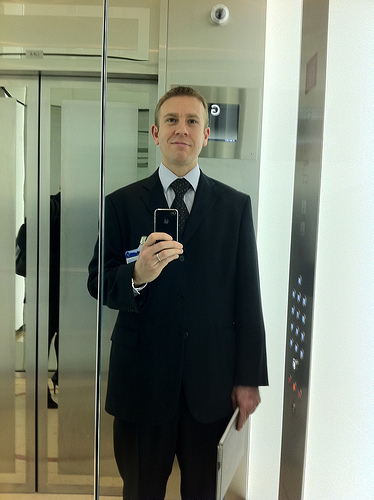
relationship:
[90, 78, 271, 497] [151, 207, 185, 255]
man holds phone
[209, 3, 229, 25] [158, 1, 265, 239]
camera attached to wall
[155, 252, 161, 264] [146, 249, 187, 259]
ring on finger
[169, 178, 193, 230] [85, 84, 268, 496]
tie worn by human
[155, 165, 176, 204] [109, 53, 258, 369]
shirt worn by human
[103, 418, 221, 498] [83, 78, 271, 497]
pants worn by man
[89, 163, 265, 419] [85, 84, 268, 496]
jacket worn by human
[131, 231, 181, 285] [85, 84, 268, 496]
hand belongs to human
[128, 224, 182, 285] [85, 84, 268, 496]
hand belongs to human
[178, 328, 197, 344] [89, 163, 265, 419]
button attached to jacket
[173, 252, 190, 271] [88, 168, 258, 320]
button attached to jacket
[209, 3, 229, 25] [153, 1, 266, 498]
camera on wall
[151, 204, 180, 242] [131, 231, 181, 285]
phone held by hand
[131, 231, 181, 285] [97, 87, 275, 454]
hand of human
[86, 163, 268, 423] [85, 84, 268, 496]
jacket worn by human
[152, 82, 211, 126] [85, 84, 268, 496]
hair belongs to human